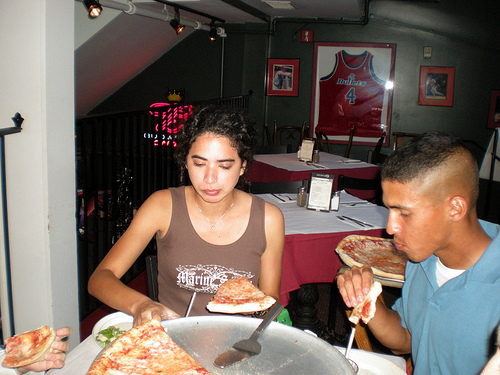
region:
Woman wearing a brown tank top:
[117, 100, 293, 322]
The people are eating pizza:
[136, 100, 486, 360]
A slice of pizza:
[90, 320, 180, 370]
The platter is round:
[90, 307, 345, 369]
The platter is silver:
[85, 302, 345, 367]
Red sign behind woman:
[141, 92, 187, 142]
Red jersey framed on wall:
[312, 30, 392, 150]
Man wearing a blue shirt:
[360, 126, 492, 366]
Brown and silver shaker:
[293, 181, 309, 208]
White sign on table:
[303, 167, 333, 212]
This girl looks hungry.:
[162, 98, 273, 209]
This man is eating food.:
[378, 144, 496, 275]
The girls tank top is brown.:
[154, 191, 277, 287]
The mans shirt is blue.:
[396, 255, 498, 366]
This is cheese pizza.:
[105, 313, 201, 370]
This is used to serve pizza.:
[218, 311, 301, 371]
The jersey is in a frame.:
[305, 30, 390, 140]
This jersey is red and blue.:
[310, 52, 387, 152]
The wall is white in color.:
[22, 30, 69, 246]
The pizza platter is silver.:
[261, 330, 324, 371]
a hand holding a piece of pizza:
[1, 325, 76, 374]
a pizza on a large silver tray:
[86, 315, 356, 373]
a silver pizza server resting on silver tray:
[214, 303, 286, 370]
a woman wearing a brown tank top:
[86, 100, 285, 326]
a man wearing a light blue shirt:
[335, 133, 499, 373]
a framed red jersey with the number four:
[308, 37, 398, 149]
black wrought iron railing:
[74, 91, 254, 317]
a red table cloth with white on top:
[253, 190, 396, 307]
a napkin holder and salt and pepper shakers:
[296, 171, 340, 213]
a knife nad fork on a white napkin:
[335, 211, 377, 233]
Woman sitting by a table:
[87, 104, 285, 326]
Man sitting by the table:
[337, 131, 498, 373]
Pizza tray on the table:
[91, 315, 356, 374]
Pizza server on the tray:
[213, 303, 285, 367]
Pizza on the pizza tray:
[87, 319, 212, 372]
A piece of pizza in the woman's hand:
[206, 275, 276, 312]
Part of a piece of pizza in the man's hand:
[346, 279, 382, 325]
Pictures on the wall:
[265, 42, 455, 147]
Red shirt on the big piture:
[318, 51, 381, 136]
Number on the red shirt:
[343, 87, 358, 104]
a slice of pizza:
[202, 274, 272, 313]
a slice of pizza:
[2, 323, 57, 370]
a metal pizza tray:
[88, 316, 351, 373]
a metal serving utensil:
[212, 298, 284, 370]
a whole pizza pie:
[336, 232, 406, 280]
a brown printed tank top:
[153, 185, 263, 317]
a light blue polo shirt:
[398, 217, 495, 373]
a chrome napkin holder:
[305, 168, 333, 213]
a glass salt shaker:
[329, 188, 340, 210]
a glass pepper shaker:
[296, 182, 307, 206]